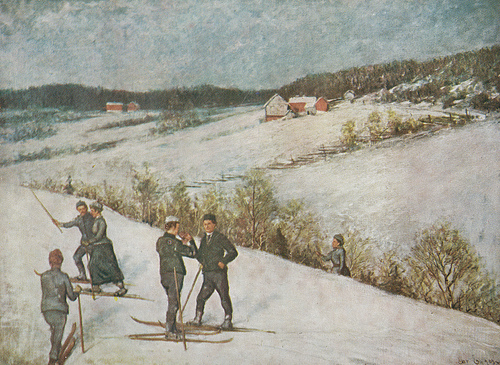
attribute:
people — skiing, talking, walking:
[43, 179, 252, 345]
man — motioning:
[194, 216, 242, 317]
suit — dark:
[199, 225, 246, 309]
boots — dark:
[187, 304, 231, 331]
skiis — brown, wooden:
[167, 306, 220, 351]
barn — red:
[270, 87, 327, 119]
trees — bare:
[404, 224, 466, 286]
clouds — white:
[153, 20, 222, 65]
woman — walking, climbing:
[82, 205, 130, 285]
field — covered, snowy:
[288, 121, 465, 232]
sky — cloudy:
[87, 27, 306, 67]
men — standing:
[165, 203, 240, 300]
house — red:
[104, 99, 142, 117]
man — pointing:
[58, 204, 100, 249]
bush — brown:
[374, 249, 416, 284]